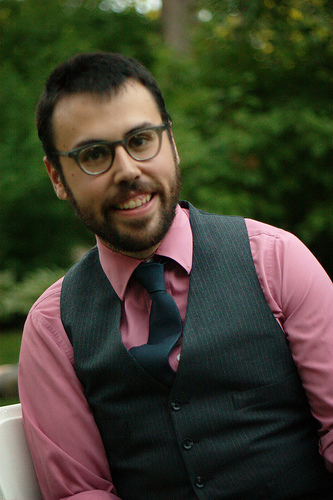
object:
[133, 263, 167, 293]
knot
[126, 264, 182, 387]
tie